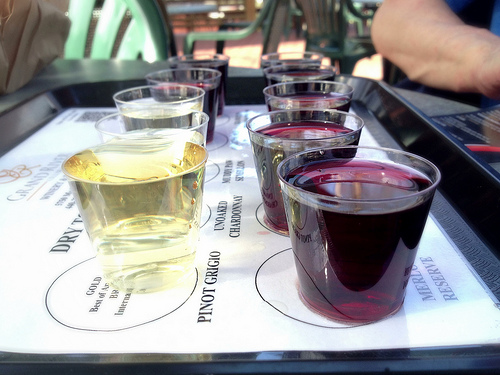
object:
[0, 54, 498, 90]
table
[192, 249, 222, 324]
name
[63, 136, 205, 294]
white wine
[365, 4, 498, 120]
arm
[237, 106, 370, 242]
glass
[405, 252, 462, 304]
name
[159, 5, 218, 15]
table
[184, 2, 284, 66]
chair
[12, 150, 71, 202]
name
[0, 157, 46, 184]
logo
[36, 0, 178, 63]
chair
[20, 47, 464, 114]
table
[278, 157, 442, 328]
wine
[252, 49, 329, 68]
glass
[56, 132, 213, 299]
glass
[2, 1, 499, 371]
wine bar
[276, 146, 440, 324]
glass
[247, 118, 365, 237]
wine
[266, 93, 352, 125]
wine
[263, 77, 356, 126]
glass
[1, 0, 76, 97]
jacket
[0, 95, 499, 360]
mat